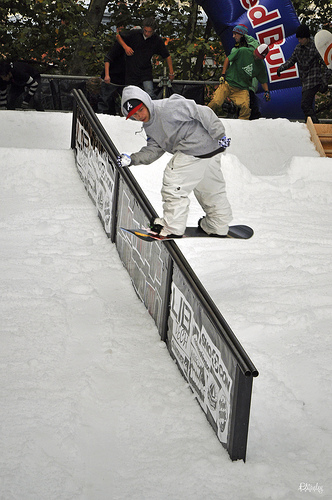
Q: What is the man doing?
A: Riding a snowboard.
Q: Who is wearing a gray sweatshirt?
A: The snowboarder.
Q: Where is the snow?
A: On the ground.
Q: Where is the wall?
A: Beneath the snowboarder.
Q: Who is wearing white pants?
A: The snowboarder.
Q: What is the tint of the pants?
A: White.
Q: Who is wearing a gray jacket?
A: A man.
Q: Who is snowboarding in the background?
A: A person.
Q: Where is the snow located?
A: Beneath the snowboarder.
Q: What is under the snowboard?
A: A rail.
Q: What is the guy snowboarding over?
A: A sign.